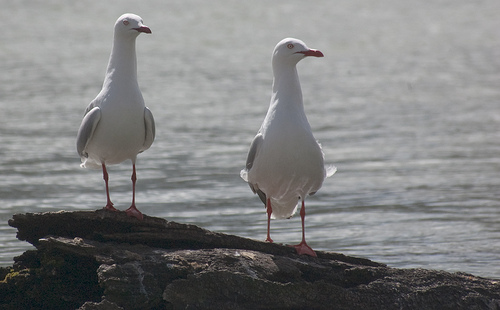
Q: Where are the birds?
A: On the rock.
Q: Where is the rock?
A: Below the birds.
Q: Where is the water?
A: Behind the birds.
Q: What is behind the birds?
A: Water.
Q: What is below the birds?
A: A rock.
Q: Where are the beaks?
A: On the birds.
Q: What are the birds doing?
A: Standing on a rock.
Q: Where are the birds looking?
A: To the right.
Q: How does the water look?
A: Calm.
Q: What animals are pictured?
A: Birds.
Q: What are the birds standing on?
A: Log.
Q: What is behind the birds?
A: Water.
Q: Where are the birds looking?
A: Right.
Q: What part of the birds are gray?
A: Wings.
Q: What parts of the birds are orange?
A: Feet.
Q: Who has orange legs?
A: Seagull.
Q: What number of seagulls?
A: Two.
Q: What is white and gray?
A: Seagulls.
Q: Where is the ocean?
A: Behind the seagulls.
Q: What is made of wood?
A: Log.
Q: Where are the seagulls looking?
A: Right.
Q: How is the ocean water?
A: Ripply.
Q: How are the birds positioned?
A: Standing.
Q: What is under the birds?
A: A rotten log.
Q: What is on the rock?
A: Seagulls.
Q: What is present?
A: Animals.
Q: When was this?
A: Daytime.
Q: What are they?
A: Birds.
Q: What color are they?
A: White.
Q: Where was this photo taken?
A: Near two birds.